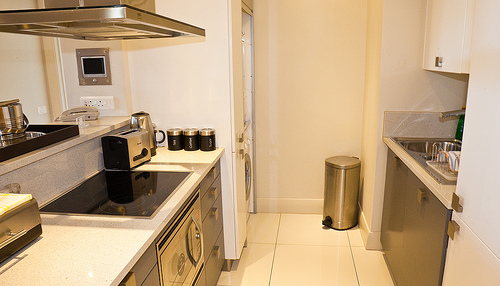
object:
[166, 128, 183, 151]
canister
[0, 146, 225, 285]
counter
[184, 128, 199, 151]
canister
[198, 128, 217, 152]
canister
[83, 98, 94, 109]
outlets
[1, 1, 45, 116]
wall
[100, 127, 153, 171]
toaster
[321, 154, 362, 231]
trash can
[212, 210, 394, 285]
floor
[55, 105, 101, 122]
phone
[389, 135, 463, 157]
sink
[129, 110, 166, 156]
cofee maker